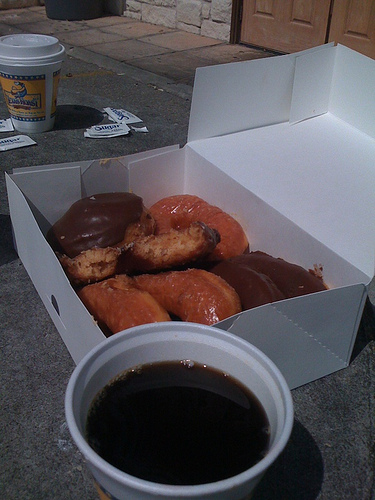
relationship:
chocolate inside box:
[46, 190, 142, 257] [4, 39, 373, 388]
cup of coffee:
[64, 318, 294, 499] [86, 360, 269, 486]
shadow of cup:
[49, 102, 104, 130] [0, 34, 66, 133]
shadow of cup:
[245, 413, 323, 499] [64, 318, 294, 499]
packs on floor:
[82, 102, 148, 138] [0, 1, 374, 498]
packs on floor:
[0, 118, 37, 152] [0, 1, 374, 498]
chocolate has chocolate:
[46, 190, 142, 257] [43, 192, 142, 255]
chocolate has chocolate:
[209, 250, 325, 310] [209, 251, 325, 311]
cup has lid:
[0, 34, 66, 133] [1, 34, 66, 67]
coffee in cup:
[86, 360, 269, 486] [64, 318, 294, 499]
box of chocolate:
[4, 39, 373, 388] [46, 190, 142, 257]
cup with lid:
[0, 34, 66, 133] [1, 34, 66, 67]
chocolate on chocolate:
[43, 192, 142, 255] [46, 190, 142, 257]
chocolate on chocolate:
[209, 251, 325, 311] [209, 250, 325, 310]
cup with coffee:
[64, 318, 294, 499] [86, 360, 269, 486]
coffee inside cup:
[86, 360, 269, 486] [64, 318, 294, 499]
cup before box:
[64, 318, 294, 499] [4, 39, 373, 388]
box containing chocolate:
[4, 39, 373, 388] [46, 190, 142, 257]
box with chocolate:
[4, 39, 373, 388] [46, 190, 142, 257]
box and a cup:
[4, 39, 373, 388] [64, 318, 294, 499]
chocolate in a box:
[46, 190, 142, 257] [4, 39, 373, 388]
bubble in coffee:
[181, 357, 194, 372] [86, 360, 269, 486]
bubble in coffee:
[111, 364, 146, 384] [86, 360, 269, 486]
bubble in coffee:
[261, 422, 271, 435] [86, 360, 269, 486]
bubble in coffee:
[84, 385, 107, 416] [86, 360, 269, 486]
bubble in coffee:
[88, 434, 101, 456] [86, 360, 269, 486]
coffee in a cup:
[86, 360, 269, 486] [64, 318, 294, 499]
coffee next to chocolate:
[86, 360, 269, 486] [46, 190, 142, 257]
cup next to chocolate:
[64, 318, 294, 499] [46, 190, 142, 257]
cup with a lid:
[0, 34, 66, 133] [1, 34, 66, 67]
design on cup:
[1, 69, 61, 123] [0, 34, 66, 133]